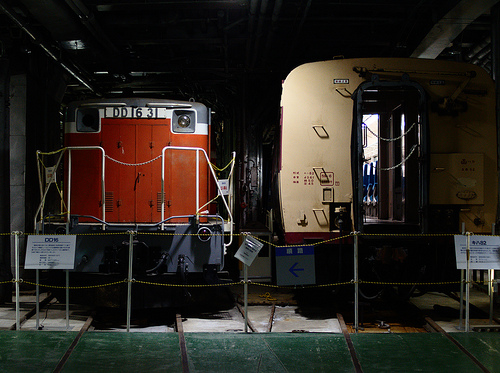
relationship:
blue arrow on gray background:
[276, 252, 317, 287] [266, 232, 461, 324]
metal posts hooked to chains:
[122, 231, 137, 328] [138, 228, 240, 294]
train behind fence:
[43, 86, 225, 309] [9, 222, 498, 332]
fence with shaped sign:
[9, 222, 498, 332] [24, 235, 77, 270]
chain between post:
[103, 147, 165, 176] [152, 140, 177, 232]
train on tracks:
[43, 86, 225, 309] [74, 323, 194, 355]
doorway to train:
[351, 83, 436, 227] [266, 59, 498, 246]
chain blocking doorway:
[371, 134, 458, 196] [357, 82, 428, 232]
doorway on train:
[357, 82, 428, 232] [234, 53, 486, 304]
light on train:
[172, 114, 192, 129] [56, 91, 227, 316]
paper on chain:
[233, 232, 261, 273] [18, 226, 498, 253]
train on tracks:
[35, 74, 290, 346] [6, 281, 471, 368]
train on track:
[236, 40, 480, 314] [262, 272, 497, 364]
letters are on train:
[101, 101, 163, 121] [21, 96, 260, 337]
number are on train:
[96, 102, 166, 115] [21, 96, 260, 337]